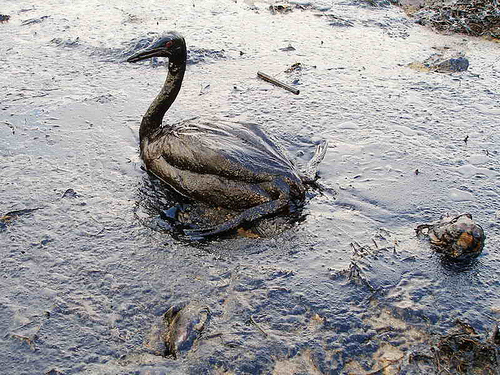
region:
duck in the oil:
[94, 23, 321, 248]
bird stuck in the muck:
[114, 28, 316, 240]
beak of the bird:
[123, 48, 150, 61]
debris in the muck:
[16, 7, 481, 362]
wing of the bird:
[165, 131, 280, 182]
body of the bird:
[150, 123, 285, 194]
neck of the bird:
[135, 78, 195, 125]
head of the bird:
[150, 31, 190, 63]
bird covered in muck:
[123, 30, 306, 237]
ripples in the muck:
[7, 19, 477, 338]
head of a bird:
[128, 25, 199, 66]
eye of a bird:
[160, 38, 180, 48]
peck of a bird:
[115, 48, 152, 73]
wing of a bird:
[153, 118, 285, 193]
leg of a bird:
[180, 190, 288, 248]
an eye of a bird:
[162, 37, 179, 47]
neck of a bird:
[140, 70, 203, 127]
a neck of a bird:
[133, 67, 199, 139]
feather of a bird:
[185, 142, 312, 204]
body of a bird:
[176, 117, 328, 205]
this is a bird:
[109, 7, 320, 245]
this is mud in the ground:
[126, 257, 234, 359]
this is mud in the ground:
[383, 170, 427, 246]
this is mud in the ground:
[257, 270, 340, 347]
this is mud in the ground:
[59, 128, 130, 233]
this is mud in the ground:
[60, 242, 147, 344]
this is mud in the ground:
[326, 91, 416, 191]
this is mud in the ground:
[24, 67, 120, 210]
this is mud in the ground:
[349, 247, 429, 339]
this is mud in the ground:
[84, 195, 149, 265]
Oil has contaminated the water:
[2, 0, 499, 372]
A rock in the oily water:
[163, 302, 209, 350]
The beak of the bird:
[131, 43, 158, 62]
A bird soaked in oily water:
[129, 32, 309, 242]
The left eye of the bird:
[164, 37, 174, 47]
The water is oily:
[1, 1, 498, 374]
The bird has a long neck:
[142, 62, 184, 131]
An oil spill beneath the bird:
[2, 0, 499, 373]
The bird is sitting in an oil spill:
[128, 32, 304, 240]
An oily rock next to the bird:
[163, 300, 210, 357]